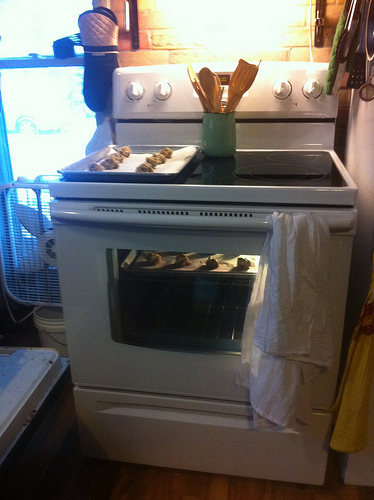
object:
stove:
[59, 65, 356, 488]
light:
[249, 255, 259, 272]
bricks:
[138, 9, 166, 30]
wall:
[136, 1, 315, 46]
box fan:
[0, 173, 66, 308]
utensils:
[223, 58, 260, 114]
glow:
[151, 1, 314, 63]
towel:
[233, 208, 337, 433]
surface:
[58, 149, 350, 189]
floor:
[9, 464, 134, 500]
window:
[0, 0, 98, 240]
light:
[4, 66, 83, 179]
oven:
[49, 197, 359, 412]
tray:
[121, 249, 264, 278]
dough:
[144, 249, 253, 272]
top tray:
[57, 143, 199, 182]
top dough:
[86, 144, 174, 176]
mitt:
[75, 6, 121, 114]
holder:
[199, 110, 237, 160]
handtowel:
[328, 254, 374, 456]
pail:
[30, 305, 69, 357]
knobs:
[124, 80, 145, 103]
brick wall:
[119, 0, 329, 63]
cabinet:
[337, 0, 373, 488]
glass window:
[105, 245, 262, 357]